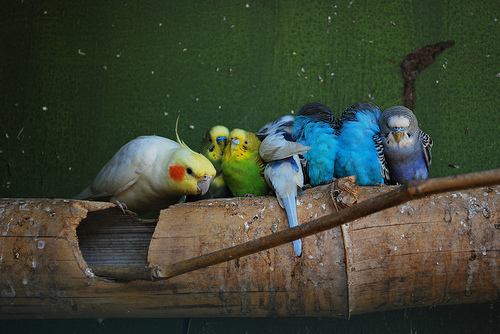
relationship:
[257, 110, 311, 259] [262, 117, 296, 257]
bird have feathers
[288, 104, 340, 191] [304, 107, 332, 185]
bird have feathers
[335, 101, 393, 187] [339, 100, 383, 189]
bird have feathers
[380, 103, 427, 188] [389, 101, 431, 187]
bird have feathers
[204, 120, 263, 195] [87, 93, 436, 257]
lovebirds below birds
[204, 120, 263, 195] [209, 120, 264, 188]
lovebirds of lovebirds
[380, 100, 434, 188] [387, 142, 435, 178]
bird with body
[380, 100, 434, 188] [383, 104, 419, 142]
bird with head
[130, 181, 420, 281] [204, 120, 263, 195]
crack in lovebirds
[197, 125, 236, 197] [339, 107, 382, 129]
bird with tucked in head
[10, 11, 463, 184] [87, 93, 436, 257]
fabric behind birds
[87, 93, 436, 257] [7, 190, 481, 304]
birds on a log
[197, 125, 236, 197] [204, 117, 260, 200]
bird huddled together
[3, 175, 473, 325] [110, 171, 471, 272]
wood log with stick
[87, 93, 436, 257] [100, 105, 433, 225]
birds perched together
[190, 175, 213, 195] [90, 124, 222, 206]
beak of bird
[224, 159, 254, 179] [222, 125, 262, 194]
chest of bird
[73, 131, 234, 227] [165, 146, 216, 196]
bird with head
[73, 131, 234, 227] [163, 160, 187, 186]
bird with cheek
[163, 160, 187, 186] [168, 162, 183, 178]
cheek with spot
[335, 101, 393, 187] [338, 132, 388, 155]
bird with wings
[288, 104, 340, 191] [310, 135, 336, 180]
bird with wings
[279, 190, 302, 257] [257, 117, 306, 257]
bird tail of bird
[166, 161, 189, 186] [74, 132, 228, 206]
spot on bird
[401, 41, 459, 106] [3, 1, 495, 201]
spot on wall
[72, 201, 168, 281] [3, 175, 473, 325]
hole in wood log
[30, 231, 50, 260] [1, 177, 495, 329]
spot on branch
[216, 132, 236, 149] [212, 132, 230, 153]
spot above beak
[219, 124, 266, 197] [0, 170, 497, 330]
bird on log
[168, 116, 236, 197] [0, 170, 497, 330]
bird on log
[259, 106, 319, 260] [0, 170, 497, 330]
bird on log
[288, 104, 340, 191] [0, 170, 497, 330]
bird on log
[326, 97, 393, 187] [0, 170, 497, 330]
bird on log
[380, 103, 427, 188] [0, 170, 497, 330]
bird on log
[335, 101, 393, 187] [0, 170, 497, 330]
bird on log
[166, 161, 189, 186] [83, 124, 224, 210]
spot on face of bird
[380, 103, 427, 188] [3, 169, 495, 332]
bird on trunk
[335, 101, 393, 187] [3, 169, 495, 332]
bird on trunk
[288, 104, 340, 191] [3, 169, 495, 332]
bird on trunk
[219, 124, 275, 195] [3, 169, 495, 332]
bird sitting on trunk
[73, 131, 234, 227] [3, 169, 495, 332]
bird sitting on trunk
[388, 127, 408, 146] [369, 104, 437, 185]
beak on bird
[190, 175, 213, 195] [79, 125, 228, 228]
beak on bird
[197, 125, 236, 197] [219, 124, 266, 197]
bird huddled next to bird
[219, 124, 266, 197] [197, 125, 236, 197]
bird huddled next to bird